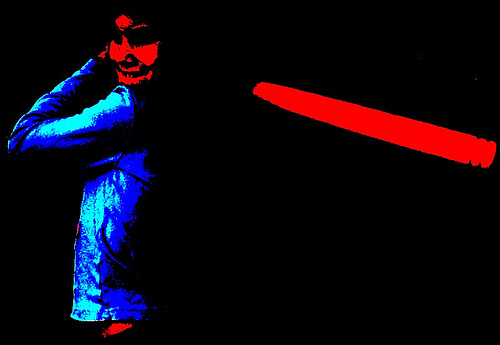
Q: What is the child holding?
A: Bat.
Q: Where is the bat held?
A: Hands.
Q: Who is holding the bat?
A: A girl.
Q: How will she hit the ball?
A: Bat.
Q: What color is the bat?
A: Red.